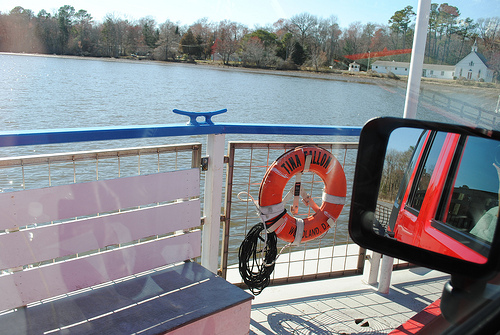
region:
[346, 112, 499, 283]
THE SIDE MIRROR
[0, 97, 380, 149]
THE TOP OF THE RAIL IS BLUE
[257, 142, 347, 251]
THE LIFE SAVER IS ORANGE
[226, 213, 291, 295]
THE ROPE IS BLACK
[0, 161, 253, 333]
THE BENCH IS WHITE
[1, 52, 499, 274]
THE WATER IS CALM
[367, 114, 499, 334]
THE CAR IS RED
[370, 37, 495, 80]
THE CHURCH IS WHITE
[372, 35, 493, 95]
THE BUILDING IS A CHURCH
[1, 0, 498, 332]
THE FERRY IS ON THE WATER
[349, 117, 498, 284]
A drivers side mirror.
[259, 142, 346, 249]
A round flotation device.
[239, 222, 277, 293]
A black rope.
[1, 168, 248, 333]
A bench.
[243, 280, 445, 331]
A shadow on the ground.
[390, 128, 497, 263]
A reflection of the red vehicle.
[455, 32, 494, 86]
A small white church.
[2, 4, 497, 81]
Trees which are almost bare.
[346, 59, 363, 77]
A white gazebo.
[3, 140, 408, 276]
A silver fence.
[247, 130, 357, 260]
a orange life preservers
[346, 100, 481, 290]
a rear view mirror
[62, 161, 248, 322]
a wooden bench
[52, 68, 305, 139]
a body of water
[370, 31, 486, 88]
a white church with a steeple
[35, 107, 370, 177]
a blue railing on a boat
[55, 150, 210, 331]
a pink wooden bench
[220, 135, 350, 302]
a metal gate on a boat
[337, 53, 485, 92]
a white gazebo by a church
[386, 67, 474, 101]
a wooden fence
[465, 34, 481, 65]
the church has a steeple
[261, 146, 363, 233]
the life tube is orange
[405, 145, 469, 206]
the vehicle is reflecting in the mirror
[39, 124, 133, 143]
the railing is blue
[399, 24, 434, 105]
this pole is white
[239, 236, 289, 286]
the rope is black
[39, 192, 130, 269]
the bench is white in color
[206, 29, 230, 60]
this tree has red leaves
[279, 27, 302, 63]
this tree has green leaves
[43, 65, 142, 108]
the water is blue in color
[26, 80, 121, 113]
The water is blue.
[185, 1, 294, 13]
The sky is blue.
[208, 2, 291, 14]
The sky is clear.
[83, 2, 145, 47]
The trees have no leaves.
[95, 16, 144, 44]
The trees are brown.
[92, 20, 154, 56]
Trees are in the background.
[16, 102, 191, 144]
The rail is blue.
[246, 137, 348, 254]
The life preserver is orange.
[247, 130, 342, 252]
The life preserver is round.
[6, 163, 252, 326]
The bench is white.